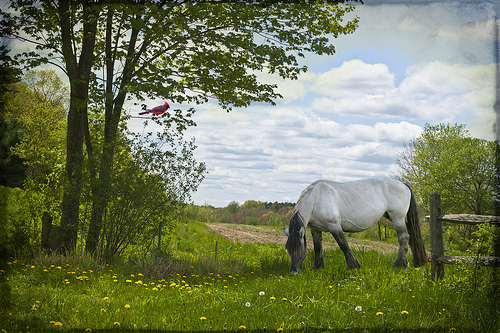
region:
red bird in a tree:
[136, 95, 181, 122]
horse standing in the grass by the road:
[274, 168, 429, 288]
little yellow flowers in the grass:
[59, 263, 201, 302]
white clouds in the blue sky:
[310, 60, 457, 140]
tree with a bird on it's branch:
[30, 14, 204, 257]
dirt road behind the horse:
[209, 211, 277, 261]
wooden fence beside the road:
[420, 175, 497, 276]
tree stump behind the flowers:
[36, 208, 59, 260]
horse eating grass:
[261, 198, 326, 293]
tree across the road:
[404, 120, 492, 222]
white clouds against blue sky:
[0, 0, 61, 54]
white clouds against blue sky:
[370, 19, 433, 90]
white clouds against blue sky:
[439, 28, 482, 97]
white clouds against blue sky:
[308, 60, 368, 117]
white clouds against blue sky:
[376, 68, 496, 125]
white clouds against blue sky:
[236, 112, 307, 153]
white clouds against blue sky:
[314, 120, 396, 165]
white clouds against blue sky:
[211, 132, 247, 177]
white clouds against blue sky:
[225, 168, 282, 193]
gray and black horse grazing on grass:
[271, 163, 413, 268]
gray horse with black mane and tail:
[282, 172, 427, 277]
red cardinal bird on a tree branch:
[136, 100, 173, 119]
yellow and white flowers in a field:
[3, 248, 498, 328]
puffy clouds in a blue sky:
[132, 5, 494, 210]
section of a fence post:
[420, 186, 497, 288]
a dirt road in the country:
[198, 216, 434, 264]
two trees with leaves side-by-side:
[2, 3, 366, 263]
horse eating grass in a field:
[278, 170, 430, 278]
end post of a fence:
[423, 186, 447, 286]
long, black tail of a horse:
[401, 185, 428, 270]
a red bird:
[131, 95, 176, 127]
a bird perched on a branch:
[136, 94, 182, 125]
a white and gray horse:
[273, 137, 433, 283]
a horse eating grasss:
[256, 159, 447, 283]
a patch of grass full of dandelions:
[39, 253, 450, 326]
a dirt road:
[201, 211, 496, 284]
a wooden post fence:
[404, 178, 499, 290]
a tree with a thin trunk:
[58, 30, 94, 261]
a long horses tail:
[386, 180, 446, 277]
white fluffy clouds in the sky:
[294, 60, 488, 145]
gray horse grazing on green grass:
[276, 171, 430, 261]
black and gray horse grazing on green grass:
[263, 168, 440, 283]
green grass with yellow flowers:
[23, 265, 87, 303]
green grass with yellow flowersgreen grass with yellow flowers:
[113, 251, 155, 295]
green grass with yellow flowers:
[166, 276, 210, 310]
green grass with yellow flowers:
[175, 301, 226, 332]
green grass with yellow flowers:
[220, 265, 265, 305]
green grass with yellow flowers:
[249, 279, 301, 316]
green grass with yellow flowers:
[295, 289, 363, 321]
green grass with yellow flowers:
[362, 293, 430, 327]